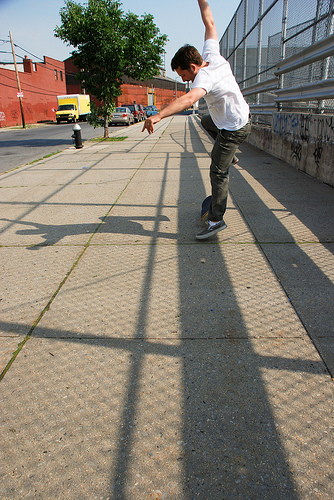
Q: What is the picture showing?
A: It is showing a sidewalk.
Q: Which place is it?
A: It is a sidewalk.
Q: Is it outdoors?
A: Yes, it is outdoors.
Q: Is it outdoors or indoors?
A: It is outdoors.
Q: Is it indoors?
A: No, it is outdoors.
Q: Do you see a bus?
A: No, there are no buses.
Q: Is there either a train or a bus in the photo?
A: No, there are no buses or trains.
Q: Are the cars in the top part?
A: Yes, the cars are in the top of the image.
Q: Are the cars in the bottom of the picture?
A: No, the cars are in the top of the image.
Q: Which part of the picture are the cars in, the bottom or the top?
A: The cars are in the top of the image.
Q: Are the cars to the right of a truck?
A: Yes, the cars are to the right of a truck.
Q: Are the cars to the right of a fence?
A: No, the cars are to the right of a truck.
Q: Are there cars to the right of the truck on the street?
A: Yes, there are cars to the right of the truck.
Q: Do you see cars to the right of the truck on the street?
A: Yes, there are cars to the right of the truck.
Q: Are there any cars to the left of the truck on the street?
A: No, the cars are to the right of the truck.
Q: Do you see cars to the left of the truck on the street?
A: No, the cars are to the right of the truck.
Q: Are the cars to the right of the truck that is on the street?
A: Yes, the cars are to the right of the truck.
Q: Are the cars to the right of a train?
A: No, the cars are to the right of the truck.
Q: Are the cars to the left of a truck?
A: No, the cars are to the right of a truck.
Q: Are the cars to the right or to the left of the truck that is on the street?
A: The cars are to the right of the truck.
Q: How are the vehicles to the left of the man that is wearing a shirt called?
A: The vehicles are cars.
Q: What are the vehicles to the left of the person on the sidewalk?
A: The vehicles are cars.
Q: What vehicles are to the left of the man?
A: The vehicles are cars.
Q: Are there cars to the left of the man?
A: Yes, there are cars to the left of the man.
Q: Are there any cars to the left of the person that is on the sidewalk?
A: Yes, there are cars to the left of the man.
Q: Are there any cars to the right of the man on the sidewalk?
A: No, the cars are to the left of the man.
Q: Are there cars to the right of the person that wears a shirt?
A: No, the cars are to the left of the man.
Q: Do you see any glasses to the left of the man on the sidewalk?
A: No, there are cars to the left of the man.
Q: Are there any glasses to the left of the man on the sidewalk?
A: No, there are cars to the left of the man.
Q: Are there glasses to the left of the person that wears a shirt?
A: No, there are cars to the left of the man.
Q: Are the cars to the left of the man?
A: Yes, the cars are to the left of the man.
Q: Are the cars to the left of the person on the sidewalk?
A: Yes, the cars are to the left of the man.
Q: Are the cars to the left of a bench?
A: No, the cars are to the left of the man.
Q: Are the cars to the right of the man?
A: No, the cars are to the left of the man.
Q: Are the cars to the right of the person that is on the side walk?
A: No, the cars are to the left of the man.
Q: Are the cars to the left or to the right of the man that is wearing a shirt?
A: The cars are to the left of the man.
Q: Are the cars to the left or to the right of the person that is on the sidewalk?
A: The cars are to the left of the man.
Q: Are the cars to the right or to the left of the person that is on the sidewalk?
A: The cars are to the left of the man.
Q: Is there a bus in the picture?
A: No, there are no buses.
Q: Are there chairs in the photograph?
A: No, there are no chairs.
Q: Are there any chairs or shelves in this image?
A: No, there are no chairs or shelves.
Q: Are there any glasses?
A: No, there are no glasses.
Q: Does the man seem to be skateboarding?
A: Yes, the man is skateboarding.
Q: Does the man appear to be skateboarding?
A: Yes, the man is skateboarding.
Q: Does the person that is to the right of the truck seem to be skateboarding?
A: Yes, the man is skateboarding.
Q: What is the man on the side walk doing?
A: The man is skateboarding.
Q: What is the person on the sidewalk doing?
A: The man is skateboarding.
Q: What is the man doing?
A: The man is skateboarding.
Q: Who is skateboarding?
A: The man is skateboarding.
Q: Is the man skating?
A: No, the man is skateboarding.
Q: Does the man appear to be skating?
A: No, the man is skateboarding.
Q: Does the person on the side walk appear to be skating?
A: No, the man is skateboarding.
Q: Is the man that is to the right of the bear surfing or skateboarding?
A: The man is skateboarding.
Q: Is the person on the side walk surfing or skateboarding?
A: The man is skateboarding.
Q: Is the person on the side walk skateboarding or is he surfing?
A: The man is skateboarding.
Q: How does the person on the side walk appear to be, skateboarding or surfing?
A: The man is skateboarding.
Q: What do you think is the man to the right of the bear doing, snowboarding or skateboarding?
A: The man is skateboarding.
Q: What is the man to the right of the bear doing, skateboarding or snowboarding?
A: The man is skateboarding.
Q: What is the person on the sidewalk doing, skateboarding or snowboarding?
A: The man is skateboarding.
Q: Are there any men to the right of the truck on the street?
A: Yes, there is a man to the right of the truck.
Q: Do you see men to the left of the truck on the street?
A: No, the man is to the right of the truck.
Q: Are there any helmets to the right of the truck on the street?
A: No, there is a man to the right of the truck.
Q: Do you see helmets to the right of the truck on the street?
A: No, there is a man to the right of the truck.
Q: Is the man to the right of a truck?
A: Yes, the man is to the right of a truck.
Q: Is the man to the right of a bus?
A: No, the man is to the right of a truck.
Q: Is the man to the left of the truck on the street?
A: No, the man is to the right of the truck.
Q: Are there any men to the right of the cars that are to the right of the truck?
A: Yes, there is a man to the right of the cars.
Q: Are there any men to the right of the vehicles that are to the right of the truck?
A: Yes, there is a man to the right of the cars.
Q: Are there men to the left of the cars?
A: No, the man is to the right of the cars.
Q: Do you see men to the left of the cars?
A: No, the man is to the right of the cars.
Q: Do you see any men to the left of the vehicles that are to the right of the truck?
A: No, the man is to the right of the cars.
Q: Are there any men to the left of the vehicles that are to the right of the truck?
A: No, the man is to the right of the cars.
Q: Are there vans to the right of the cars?
A: No, there is a man to the right of the cars.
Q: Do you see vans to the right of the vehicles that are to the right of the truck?
A: No, there is a man to the right of the cars.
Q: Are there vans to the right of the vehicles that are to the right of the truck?
A: No, there is a man to the right of the cars.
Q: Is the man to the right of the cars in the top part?
A: Yes, the man is to the right of the cars.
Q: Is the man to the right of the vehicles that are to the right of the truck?
A: Yes, the man is to the right of the cars.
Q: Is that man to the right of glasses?
A: No, the man is to the right of the cars.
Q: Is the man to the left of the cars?
A: No, the man is to the right of the cars.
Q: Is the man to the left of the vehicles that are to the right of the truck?
A: No, the man is to the right of the cars.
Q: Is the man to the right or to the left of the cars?
A: The man is to the right of the cars.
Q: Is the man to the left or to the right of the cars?
A: The man is to the right of the cars.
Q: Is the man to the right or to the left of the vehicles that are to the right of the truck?
A: The man is to the right of the cars.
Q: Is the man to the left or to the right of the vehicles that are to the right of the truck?
A: The man is to the right of the cars.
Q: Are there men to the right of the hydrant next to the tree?
A: Yes, there is a man to the right of the fire hydrant.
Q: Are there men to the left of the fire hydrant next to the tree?
A: No, the man is to the right of the hydrant.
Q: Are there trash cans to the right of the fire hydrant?
A: No, there is a man to the right of the fire hydrant.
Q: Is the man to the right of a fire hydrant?
A: Yes, the man is to the right of a fire hydrant.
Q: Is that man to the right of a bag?
A: No, the man is to the right of a fire hydrant.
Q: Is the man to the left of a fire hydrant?
A: No, the man is to the right of a fire hydrant.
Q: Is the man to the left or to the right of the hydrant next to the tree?
A: The man is to the right of the hydrant.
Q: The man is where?
A: The man is on the side walk.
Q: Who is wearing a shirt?
A: The man is wearing a shirt.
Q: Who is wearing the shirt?
A: The man is wearing a shirt.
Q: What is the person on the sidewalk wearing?
A: The man is wearing a shirt.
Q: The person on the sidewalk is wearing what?
A: The man is wearing a shirt.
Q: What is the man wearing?
A: The man is wearing a shirt.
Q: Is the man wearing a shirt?
A: Yes, the man is wearing a shirt.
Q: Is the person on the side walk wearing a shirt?
A: Yes, the man is wearing a shirt.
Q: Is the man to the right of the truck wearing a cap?
A: No, the man is wearing a shirt.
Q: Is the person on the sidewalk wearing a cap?
A: No, the man is wearing a shirt.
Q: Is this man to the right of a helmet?
A: No, the man is to the right of a truck.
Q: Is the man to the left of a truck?
A: No, the man is to the right of a truck.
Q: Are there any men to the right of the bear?
A: Yes, there is a man to the right of the bear.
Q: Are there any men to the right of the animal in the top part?
A: Yes, there is a man to the right of the bear.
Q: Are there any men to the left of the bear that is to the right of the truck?
A: No, the man is to the right of the bear.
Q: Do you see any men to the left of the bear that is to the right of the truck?
A: No, the man is to the right of the bear.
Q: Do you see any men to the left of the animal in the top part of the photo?
A: No, the man is to the right of the bear.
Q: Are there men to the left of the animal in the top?
A: No, the man is to the right of the bear.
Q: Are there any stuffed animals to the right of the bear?
A: No, there is a man to the right of the bear.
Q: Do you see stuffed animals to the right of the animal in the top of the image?
A: No, there is a man to the right of the bear.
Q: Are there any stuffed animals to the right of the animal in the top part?
A: No, there is a man to the right of the bear.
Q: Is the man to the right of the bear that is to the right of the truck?
A: Yes, the man is to the right of the bear.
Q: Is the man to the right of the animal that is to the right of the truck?
A: Yes, the man is to the right of the bear.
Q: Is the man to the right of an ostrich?
A: No, the man is to the right of the bear.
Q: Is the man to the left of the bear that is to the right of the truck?
A: No, the man is to the right of the bear.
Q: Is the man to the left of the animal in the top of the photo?
A: No, the man is to the right of the bear.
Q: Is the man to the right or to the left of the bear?
A: The man is to the right of the bear.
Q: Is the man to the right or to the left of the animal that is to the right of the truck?
A: The man is to the right of the bear.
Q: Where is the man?
A: The man is on the side walk.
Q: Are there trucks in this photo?
A: Yes, there is a truck.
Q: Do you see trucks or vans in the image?
A: Yes, there is a truck.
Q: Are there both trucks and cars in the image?
A: Yes, there are both a truck and a car.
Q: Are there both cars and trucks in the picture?
A: Yes, there are both a truck and a car.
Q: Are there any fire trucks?
A: No, there are no fire trucks.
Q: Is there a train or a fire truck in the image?
A: No, there are no fire trucks or trains.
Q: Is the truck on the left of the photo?
A: Yes, the truck is on the left of the image.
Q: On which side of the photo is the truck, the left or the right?
A: The truck is on the left of the image.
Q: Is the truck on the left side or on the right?
A: The truck is on the left of the image.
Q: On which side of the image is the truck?
A: The truck is on the left of the image.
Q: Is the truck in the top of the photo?
A: Yes, the truck is in the top of the image.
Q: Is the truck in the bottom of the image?
A: No, the truck is in the top of the image.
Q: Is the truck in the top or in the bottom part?
A: The truck is in the top of the image.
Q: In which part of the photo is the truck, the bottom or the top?
A: The truck is in the top of the image.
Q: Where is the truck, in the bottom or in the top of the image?
A: The truck is in the top of the image.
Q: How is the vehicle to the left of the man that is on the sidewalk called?
A: The vehicle is a truck.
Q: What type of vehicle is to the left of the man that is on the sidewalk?
A: The vehicle is a truck.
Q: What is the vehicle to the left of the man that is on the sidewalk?
A: The vehicle is a truck.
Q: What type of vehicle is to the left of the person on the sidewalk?
A: The vehicle is a truck.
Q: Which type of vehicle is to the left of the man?
A: The vehicle is a truck.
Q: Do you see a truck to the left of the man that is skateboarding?
A: Yes, there is a truck to the left of the man.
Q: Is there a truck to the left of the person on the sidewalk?
A: Yes, there is a truck to the left of the man.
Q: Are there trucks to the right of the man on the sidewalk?
A: No, the truck is to the left of the man.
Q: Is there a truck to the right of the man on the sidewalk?
A: No, the truck is to the left of the man.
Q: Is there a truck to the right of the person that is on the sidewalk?
A: No, the truck is to the left of the man.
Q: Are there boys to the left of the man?
A: No, there is a truck to the left of the man.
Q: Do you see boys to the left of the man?
A: No, there is a truck to the left of the man.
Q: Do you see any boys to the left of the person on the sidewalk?
A: No, there is a truck to the left of the man.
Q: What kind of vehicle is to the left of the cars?
A: The vehicle is a truck.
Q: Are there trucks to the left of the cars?
A: Yes, there is a truck to the left of the cars.